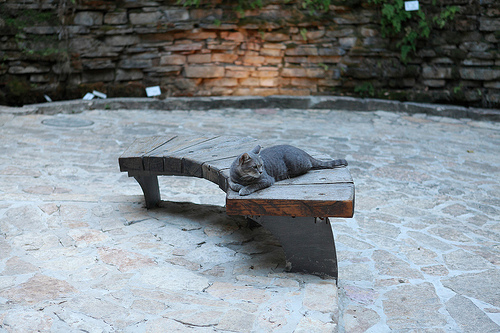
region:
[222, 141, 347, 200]
A grey cat on the bench.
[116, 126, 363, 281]
A wood bench on the ground.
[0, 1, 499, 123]
A stone wall by the bench.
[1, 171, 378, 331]
A platform on the ground.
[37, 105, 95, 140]
A man hole cover on the ground.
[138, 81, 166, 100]
A white sign on the ground.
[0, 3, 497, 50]
Green plants hanging off the wall.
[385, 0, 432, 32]
A white sign on the wall.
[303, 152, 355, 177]
A grey cat tail.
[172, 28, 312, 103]
A small sun patch on the top.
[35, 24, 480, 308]
Picture is taken outside.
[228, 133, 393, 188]
A cat laying down.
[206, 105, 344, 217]
A cat is on the bench.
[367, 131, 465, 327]
The ground is made of rocks and concrete.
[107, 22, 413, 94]
The wall is made of rocks and brick.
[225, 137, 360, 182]
The cat has stripes.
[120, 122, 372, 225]
The bench is made of wood.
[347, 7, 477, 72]
Plants are on the fence.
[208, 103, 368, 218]
There is a grey cat on the table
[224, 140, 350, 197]
A gray cat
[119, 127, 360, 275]
A cat sitting on a bench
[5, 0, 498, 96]
A brick wall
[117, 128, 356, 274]
A curved bench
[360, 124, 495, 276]
A cobbled street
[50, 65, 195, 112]
Little pieces of paper on the ground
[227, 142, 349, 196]
Cat is looking to its left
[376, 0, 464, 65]
Vegetation growing on the wall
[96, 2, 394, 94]
A wall stacked by stones.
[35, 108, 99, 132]
Manhole cover in the street.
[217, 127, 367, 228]
A cat is sitting on a bench.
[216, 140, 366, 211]
The cat is grey.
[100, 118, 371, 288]
The bench is made of wood and concrete.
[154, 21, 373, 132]
An artificial light shines its light on the wall.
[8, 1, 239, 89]
The wall is made of uneven rocks.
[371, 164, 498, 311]
The driveway is made of stones and concrete.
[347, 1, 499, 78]
Vegetation is growing on the wall.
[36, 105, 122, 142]
There is a sewer trap on the ground.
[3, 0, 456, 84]
The wall looks very old.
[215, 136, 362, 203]
The cat's attention has been caught by something.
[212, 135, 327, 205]
Cat sitting on a bench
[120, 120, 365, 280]
Wooden bench in a courtyard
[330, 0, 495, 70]
Ivy growing on a wall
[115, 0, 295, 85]
Stone wall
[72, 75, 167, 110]
Paper lying on the ground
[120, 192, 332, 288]
The bench is casting a shadow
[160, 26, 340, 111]
Light on the wall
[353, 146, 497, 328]
Stone walkway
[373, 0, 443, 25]
Paper on the ivy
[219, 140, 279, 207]
The cats ears are perked